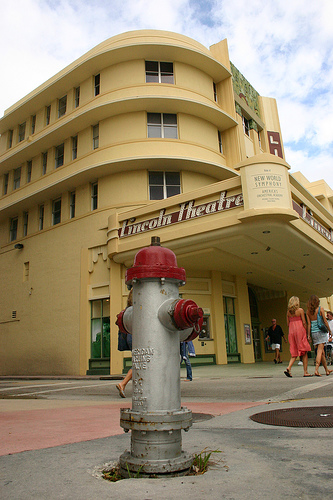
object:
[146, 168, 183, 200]
window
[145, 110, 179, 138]
window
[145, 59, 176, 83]
window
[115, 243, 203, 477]
fire hydrant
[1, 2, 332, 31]
clouds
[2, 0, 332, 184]
sky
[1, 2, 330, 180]
sky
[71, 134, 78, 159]
window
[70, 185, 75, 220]
window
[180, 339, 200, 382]
person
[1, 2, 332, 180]
clouds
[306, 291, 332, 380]
person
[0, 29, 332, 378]
building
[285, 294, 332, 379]
people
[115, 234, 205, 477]
hydrant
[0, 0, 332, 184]
clouds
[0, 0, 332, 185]
blue sky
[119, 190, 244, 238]
words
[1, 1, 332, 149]
clouds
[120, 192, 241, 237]
word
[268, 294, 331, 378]
person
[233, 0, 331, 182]
clouds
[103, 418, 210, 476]
base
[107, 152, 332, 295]
front awning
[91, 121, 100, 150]
window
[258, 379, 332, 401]
crosswalk line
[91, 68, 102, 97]
window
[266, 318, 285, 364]
person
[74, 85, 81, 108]
window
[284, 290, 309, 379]
person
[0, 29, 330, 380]
theater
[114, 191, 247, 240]
word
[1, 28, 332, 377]
theatre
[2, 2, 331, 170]
sky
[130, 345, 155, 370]
word